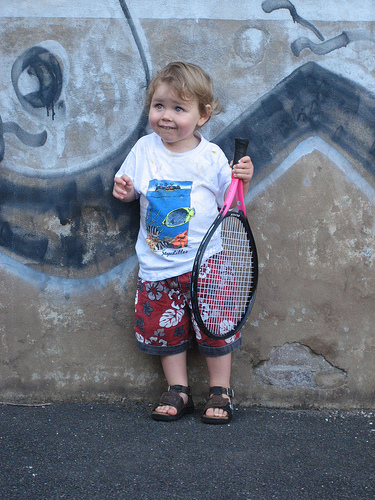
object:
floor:
[3, 408, 370, 498]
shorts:
[132, 251, 242, 357]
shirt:
[113, 129, 231, 282]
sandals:
[200, 385, 236, 426]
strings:
[200, 251, 252, 270]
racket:
[189, 135, 258, 342]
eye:
[175, 106, 185, 113]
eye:
[154, 102, 165, 110]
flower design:
[166, 281, 190, 313]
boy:
[109, 60, 255, 427]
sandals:
[148, 382, 195, 421]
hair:
[143, 61, 224, 132]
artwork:
[144, 178, 194, 258]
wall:
[0, 3, 375, 417]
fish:
[161, 207, 196, 229]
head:
[143, 58, 219, 148]